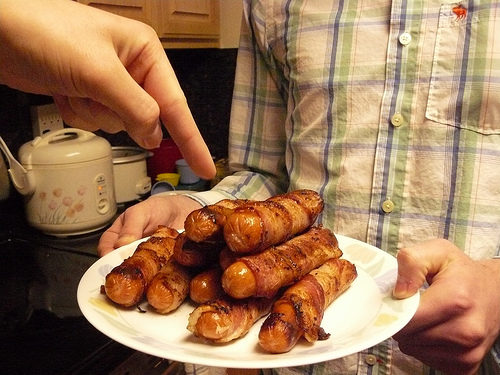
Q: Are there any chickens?
A: No, there are no chickens.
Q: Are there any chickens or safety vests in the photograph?
A: No, there are no chickens or safety vests.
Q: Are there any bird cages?
A: No, there are no bird cages.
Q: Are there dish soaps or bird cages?
A: No, there are no bird cages or dish soaps.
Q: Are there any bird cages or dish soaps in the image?
A: No, there are no bird cages or dish soaps.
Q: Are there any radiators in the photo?
A: No, there are no radiators.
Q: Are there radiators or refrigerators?
A: No, there are no radiators or refrigerators.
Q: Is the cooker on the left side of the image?
A: Yes, the cooker is on the left of the image.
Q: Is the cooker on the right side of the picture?
A: No, the cooker is on the left of the image.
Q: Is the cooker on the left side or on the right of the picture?
A: The cooker is on the left of the image.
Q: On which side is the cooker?
A: The cooker is on the left of the image.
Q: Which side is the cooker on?
A: The cooker is on the left of the image.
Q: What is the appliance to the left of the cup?
A: The appliance is a cooker.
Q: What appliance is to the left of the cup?
A: The appliance is a cooker.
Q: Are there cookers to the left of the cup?
A: Yes, there is a cooker to the left of the cup.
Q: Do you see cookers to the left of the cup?
A: Yes, there is a cooker to the left of the cup.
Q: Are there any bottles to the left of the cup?
A: No, there is a cooker to the left of the cup.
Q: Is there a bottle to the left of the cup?
A: No, there is a cooker to the left of the cup.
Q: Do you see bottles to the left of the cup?
A: No, there is a cooker to the left of the cup.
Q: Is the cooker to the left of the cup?
A: Yes, the cooker is to the left of the cup.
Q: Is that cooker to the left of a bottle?
A: No, the cooker is to the left of the cup.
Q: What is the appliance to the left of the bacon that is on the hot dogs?
A: The appliance is a cooker.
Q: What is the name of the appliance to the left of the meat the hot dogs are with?
A: The appliance is a cooker.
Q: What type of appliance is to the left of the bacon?
A: The appliance is a cooker.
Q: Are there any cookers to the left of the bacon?
A: Yes, there is a cooker to the left of the bacon.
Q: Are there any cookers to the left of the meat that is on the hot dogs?
A: Yes, there is a cooker to the left of the bacon.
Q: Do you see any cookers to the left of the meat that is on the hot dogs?
A: Yes, there is a cooker to the left of the bacon.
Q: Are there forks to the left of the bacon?
A: No, there is a cooker to the left of the bacon.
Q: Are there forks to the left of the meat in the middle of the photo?
A: No, there is a cooker to the left of the bacon.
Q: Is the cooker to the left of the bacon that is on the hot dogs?
A: Yes, the cooker is to the left of the bacon.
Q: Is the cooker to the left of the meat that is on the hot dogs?
A: Yes, the cooker is to the left of the bacon.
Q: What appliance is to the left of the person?
A: The appliance is a cooker.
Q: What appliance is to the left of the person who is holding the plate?
A: The appliance is a cooker.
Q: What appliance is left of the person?
A: The appliance is a cooker.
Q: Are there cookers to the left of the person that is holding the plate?
A: Yes, there is a cooker to the left of the person.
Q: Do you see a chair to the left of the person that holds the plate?
A: No, there is a cooker to the left of the person.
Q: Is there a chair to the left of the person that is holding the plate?
A: No, there is a cooker to the left of the person.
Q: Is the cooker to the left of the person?
A: Yes, the cooker is to the left of the person.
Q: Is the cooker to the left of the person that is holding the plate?
A: Yes, the cooker is to the left of the person.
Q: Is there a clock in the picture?
A: No, there are no clocks.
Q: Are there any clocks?
A: No, there are no clocks.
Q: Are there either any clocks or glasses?
A: No, there are no clocks or glasses.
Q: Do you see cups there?
A: Yes, there is a cup.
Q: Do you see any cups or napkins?
A: Yes, there is a cup.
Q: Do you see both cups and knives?
A: No, there is a cup but no knives.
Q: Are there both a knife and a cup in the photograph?
A: No, there is a cup but no knives.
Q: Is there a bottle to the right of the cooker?
A: No, there is a cup to the right of the cooker.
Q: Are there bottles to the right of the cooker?
A: No, there is a cup to the right of the cooker.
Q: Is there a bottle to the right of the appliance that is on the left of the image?
A: No, there is a cup to the right of the cooker.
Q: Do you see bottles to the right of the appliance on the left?
A: No, there is a cup to the right of the cooker.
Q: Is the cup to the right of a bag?
A: No, the cup is to the right of a cooker.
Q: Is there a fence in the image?
A: No, there are no fences.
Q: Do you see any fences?
A: No, there are no fences.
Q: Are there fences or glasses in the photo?
A: No, there are no fences or glasses.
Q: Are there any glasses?
A: No, there are no glasses.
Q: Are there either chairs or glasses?
A: No, there are no glasses or chairs.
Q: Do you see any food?
A: Yes, there is food.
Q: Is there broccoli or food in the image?
A: Yes, there is food.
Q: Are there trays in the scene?
A: No, there are no trays.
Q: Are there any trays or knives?
A: No, there are no trays or knives.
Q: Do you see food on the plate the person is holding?
A: Yes, there is food on the plate.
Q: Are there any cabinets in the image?
A: Yes, there is a cabinet.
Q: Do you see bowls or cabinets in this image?
A: Yes, there is a cabinet.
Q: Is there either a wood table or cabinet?
A: Yes, there is a wood cabinet.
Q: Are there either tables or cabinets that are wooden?
A: Yes, the cabinet is wooden.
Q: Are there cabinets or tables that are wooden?
A: Yes, the cabinet is wooden.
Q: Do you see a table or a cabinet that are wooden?
A: Yes, the cabinet is wooden.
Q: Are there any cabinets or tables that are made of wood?
A: Yes, the cabinet is made of wood.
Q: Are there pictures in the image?
A: No, there are no pictures.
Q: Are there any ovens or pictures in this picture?
A: No, there are no pictures or ovens.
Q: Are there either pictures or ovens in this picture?
A: No, there are no pictures or ovens.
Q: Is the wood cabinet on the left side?
A: Yes, the cabinet is on the left of the image.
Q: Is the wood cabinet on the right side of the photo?
A: No, the cabinet is on the left of the image.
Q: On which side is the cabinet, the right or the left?
A: The cabinet is on the left of the image.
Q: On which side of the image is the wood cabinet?
A: The cabinet is on the left of the image.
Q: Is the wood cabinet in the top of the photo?
A: Yes, the cabinet is in the top of the image.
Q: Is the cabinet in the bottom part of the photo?
A: No, the cabinet is in the top of the image.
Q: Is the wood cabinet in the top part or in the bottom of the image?
A: The cabinet is in the top of the image.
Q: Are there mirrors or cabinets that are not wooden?
A: No, there is a cabinet but it is wooden.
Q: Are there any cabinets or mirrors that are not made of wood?
A: No, there is a cabinet but it is made of wood.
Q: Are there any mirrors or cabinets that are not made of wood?
A: No, there is a cabinet but it is made of wood.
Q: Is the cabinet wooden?
A: Yes, the cabinet is wooden.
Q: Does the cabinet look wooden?
A: Yes, the cabinet is wooden.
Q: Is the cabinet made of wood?
A: Yes, the cabinet is made of wood.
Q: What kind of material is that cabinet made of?
A: The cabinet is made of wood.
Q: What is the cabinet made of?
A: The cabinet is made of wood.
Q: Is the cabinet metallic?
A: No, the cabinet is wooden.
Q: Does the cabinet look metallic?
A: No, the cabinet is wooden.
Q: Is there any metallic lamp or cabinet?
A: No, there is a cabinet but it is wooden.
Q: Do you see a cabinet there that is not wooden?
A: No, there is a cabinet but it is wooden.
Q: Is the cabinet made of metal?
A: No, the cabinet is made of wood.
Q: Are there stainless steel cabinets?
A: No, there is a cabinet but it is made of wood.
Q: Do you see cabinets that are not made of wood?
A: No, there is a cabinet but it is made of wood.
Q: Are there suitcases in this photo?
A: No, there are no suitcases.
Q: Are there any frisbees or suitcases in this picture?
A: No, there are no suitcases or frisbees.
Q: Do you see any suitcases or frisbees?
A: No, there are no suitcases or frisbees.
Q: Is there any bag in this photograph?
A: No, there are no bags.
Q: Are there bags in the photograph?
A: No, there are no bags.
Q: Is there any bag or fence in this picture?
A: No, there are no bags or fences.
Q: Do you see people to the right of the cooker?
A: Yes, there is a person to the right of the cooker.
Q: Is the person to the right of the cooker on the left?
A: Yes, the person is to the right of the cooker.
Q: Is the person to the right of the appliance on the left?
A: Yes, the person is to the right of the cooker.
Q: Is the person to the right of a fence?
A: No, the person is to the right of the cooker.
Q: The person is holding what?
A: The person is holding the plate.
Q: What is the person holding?
A: The person is holding the plate.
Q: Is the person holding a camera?
A: No, the person is holding the plate.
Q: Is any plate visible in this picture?
A: Yes, there is a plate.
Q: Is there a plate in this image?
A: Yes, there is a plate.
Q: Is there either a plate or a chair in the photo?
A: Yes, there is a plate.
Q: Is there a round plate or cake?
A: Yes, there is a round plate.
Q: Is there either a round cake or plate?
A: Yes, there is a round plate.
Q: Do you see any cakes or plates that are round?
A: Yes, the plate is round.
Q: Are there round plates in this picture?
A: Yes, there is a round plate.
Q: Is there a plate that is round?
A: Yes, there is a plate that is round.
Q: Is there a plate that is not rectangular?
A: Yes, there is a round plate.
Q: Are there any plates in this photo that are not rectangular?
A: Yes, there is a round plate.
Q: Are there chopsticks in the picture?
A: No, there are no chopsticks.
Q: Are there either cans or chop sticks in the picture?
A: No, there are no chop sticks or cans.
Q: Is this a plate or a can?
A: This is a plate.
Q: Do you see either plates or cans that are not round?
A: No, there is a plate but it is round.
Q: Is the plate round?
A: Yes, the plate is round.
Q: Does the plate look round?
A: Yes, the plate is round.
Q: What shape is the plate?
A: The plate is round.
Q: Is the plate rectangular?
A: No, the plate is round.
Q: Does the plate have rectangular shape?
A: No, the plate is round.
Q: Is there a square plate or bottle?
A: No, there is a plate but it is round.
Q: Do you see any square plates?
A: No, there is a plate but it is round.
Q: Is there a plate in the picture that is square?
A: No, there is a plate but it is round.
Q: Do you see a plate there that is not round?
A: No, there is a plate but it is round.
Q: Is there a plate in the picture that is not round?
A: No, there is a plate but it is round.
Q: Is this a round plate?
A: Yes, this is a round plate.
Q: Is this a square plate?
A: No, this is a round plate.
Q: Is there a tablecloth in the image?
A: No, there are no tablecloths.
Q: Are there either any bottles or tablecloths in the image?
A: No, there are no tablecloths or bottles.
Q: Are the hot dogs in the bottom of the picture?
A: Yes, the hot dogs are in the bottom of the image.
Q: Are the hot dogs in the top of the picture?
A: No, the hot dogs are in the bottom of the image.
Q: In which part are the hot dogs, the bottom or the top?
A: The hot dogs are in the bottom of the image.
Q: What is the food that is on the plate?
A: The food is hot dogs.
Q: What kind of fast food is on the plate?
A: The food is hot dogs.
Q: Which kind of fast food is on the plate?
A: The food is hot dogs.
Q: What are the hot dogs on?
A: The hot dogs are on the plate.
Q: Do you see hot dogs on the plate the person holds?
A: Yes, there are hot dogs on the plate.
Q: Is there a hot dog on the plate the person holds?
A: Yes, there are hot dogs on the plate.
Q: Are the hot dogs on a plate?
A: Yes, the hot dogs are on a plate.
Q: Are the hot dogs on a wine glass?
A: No, the hot dogs are on a plate.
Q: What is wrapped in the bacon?
A: The hot dogs are wrapped in the bacon.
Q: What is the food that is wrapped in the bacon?
A: The food is hot dogs.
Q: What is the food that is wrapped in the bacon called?
A: The food is hot dogs.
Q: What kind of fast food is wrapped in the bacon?
A: The food is hot dogs.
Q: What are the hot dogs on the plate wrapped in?
A: The hot dogs are wrapped in bacon.